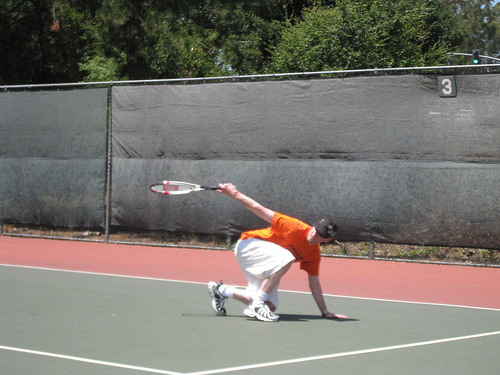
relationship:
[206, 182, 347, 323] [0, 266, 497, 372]
male playing on tennis court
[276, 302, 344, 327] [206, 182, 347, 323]
shadow on male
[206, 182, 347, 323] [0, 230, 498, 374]
male on court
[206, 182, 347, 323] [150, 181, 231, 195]
male plays tennis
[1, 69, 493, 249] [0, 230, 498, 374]
fencing around court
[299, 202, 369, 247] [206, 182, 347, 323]
hat of male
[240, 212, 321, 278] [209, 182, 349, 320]
orange shirt of tennis player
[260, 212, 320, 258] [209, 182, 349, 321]
orange shirt orange male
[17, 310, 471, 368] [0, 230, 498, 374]
lines on court